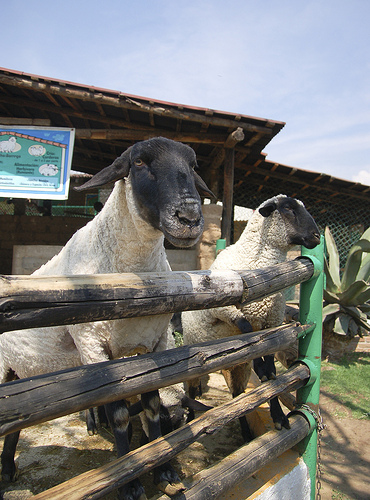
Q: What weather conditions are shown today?
A: It is clear.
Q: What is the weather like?
A: It is clear.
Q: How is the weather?
A: It is clear.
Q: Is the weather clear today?
A: Yes, it is clear.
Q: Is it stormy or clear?
A: It is clear.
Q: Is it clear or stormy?
A: It is clear.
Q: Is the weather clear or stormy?
A: It is clear.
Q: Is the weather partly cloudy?
A: No, it is clear.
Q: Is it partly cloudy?
A: No, it is clear.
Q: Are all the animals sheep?
A: Yes, all the animals are sheep.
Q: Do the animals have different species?
A: No, all the animals are sheep.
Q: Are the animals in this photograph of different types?
A: No, all the animals are sheep.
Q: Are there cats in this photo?
A: No, there are no cats.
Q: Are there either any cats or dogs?
A: No, there are no cats or dogs.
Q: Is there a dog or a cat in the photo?
A: No, there are no cats or dogs.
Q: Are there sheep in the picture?
A: Yes, there is a sheep.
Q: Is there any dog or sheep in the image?
A: Yes, there is a sheep.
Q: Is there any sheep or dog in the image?
A: Yes, there is a sheep.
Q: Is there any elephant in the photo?
A: No, there are no elephants.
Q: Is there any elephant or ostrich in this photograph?
A: No, there are no elephants or ostriches.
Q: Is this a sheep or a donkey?
A: This is a sheep.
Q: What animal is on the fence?
A: The sheep is on the fence.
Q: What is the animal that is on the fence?
A: The animal is a sheep.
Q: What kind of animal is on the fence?
A: The animal is a sheep.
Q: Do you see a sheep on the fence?
A: Yes, there is a sheep on the fence.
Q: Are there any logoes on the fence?
A: No, there is a sheep on the fence.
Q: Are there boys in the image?
A: No, there are no boys.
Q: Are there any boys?
A: No, there are no boys.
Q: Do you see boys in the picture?
A: No, there are no boys.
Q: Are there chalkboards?
A: No, there are no chalkboards.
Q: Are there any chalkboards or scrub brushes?
A: No, there are no chalkboards or scrub brushes.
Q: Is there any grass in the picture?
A: Yes, there is grass.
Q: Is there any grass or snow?
A: Yes, there is grass.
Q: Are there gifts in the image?
A: No, there are no gifts.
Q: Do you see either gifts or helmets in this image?
A: No, there are no gifts or helmets.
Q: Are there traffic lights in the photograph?
A: No, there are no traffic lights.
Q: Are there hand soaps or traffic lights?
A: No, there are no traffic lights or hand soaps.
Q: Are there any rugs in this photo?
A: No, there are no rugs.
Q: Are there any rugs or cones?
A: No, there are no rugs or cones.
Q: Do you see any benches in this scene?
A: No, there are no benches.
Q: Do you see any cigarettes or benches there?
A: No, there are no benches or cigarettes.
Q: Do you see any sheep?
A: Yes, there is a sheep.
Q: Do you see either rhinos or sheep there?
A: Yes, there is a sheep.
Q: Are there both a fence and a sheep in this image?
A: Yes, there are both a sheep and a fence.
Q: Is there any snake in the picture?
A: No, there are no snakes.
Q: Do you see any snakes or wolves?
A: No, there are no snakes or wolves.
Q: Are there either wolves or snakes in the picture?
A: No, there are no snakes or wolves.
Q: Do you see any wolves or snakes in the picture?
A: No, there are no snakes or wolves.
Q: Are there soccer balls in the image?
A: No, there are no soccer balls.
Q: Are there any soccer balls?
A: No, there are no soccer balls.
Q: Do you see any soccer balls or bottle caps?
A: No, there are no soccer balls or bottle caps.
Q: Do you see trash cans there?
A: No, there are no trash cans.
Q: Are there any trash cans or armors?
A: No, there are no trash cans or armors.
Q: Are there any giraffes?
A: No, there are no giraffes.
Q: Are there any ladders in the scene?
A: No, there are no ladders.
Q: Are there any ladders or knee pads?
A: No, there are no ladders or knee pads.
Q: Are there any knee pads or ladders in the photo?
A: No, there are no ladders or knee pads.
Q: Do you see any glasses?
A: No, there are no glasses.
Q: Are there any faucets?
A: No, there are no faucets.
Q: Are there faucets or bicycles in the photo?
A: No, there are no faucets or bicycles.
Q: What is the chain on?
A: The chain is on the post.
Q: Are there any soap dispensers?
A: No, there are no soap dispensers.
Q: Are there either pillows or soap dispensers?
A: No, there are no soap dispensers or pillows.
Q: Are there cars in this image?
A: No, there are no cars.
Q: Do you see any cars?
A: No, there are no cars.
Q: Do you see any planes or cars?
A: No, there are no cars or planes.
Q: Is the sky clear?
A: Yes, the sky is clear.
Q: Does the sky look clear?
A: Yes, the sky is clear.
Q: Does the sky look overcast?
A: No, the sky is clear.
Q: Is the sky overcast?
A: No, the sky is clear.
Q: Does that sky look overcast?
A: No, the sky is clear.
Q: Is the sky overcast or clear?
A: The sky is clear.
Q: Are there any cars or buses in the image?
A: No, there are no cars or buses.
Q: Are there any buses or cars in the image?
A: No, there are no cars or buses.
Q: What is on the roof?
A: The sign is on the roof.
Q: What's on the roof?
A: The sign is on the roof.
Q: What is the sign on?
A: The sign is on the roof.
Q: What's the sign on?
A: The sign is on the roof.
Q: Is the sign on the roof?
A: Yes, the sign is on the roof.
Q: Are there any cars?
A: No, there are no cars.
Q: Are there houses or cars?
A: No, there are no cars or houses.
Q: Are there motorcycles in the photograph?
A: No, there are no motorcycles.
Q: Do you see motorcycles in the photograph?
A: No, there are no motorcycles.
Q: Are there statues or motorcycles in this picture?
A: No, there are no motorcycles or statues.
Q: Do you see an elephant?
A: No, there are no elephants.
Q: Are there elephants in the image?
A: No, there are no elephants.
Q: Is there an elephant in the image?
A: No, there are no elephants.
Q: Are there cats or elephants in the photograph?
A: No, there are no elephants or cats.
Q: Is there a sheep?
A: Yes, there is a sheep.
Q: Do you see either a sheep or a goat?
A: Yes, there is a sheep.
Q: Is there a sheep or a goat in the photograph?
A: Yes, there is a sheep.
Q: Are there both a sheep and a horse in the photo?
A: No, there is a sheep but no horses.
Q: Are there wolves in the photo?
A: No, there are no wolves.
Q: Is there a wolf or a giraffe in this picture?
A: No, there are no wolves or giraffes.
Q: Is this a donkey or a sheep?
A: This is a sheep.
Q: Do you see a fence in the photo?
A: Yes, there is a fence.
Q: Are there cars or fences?
A: Yes, there is a fence.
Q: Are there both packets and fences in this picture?
A: No, there is a fence but no packets.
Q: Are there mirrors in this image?
A: No, there are no mirrors.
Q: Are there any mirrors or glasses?
A: No, there are no mirrors or glasses.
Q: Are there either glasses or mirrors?
A: No, there are no mirrors or glasses.